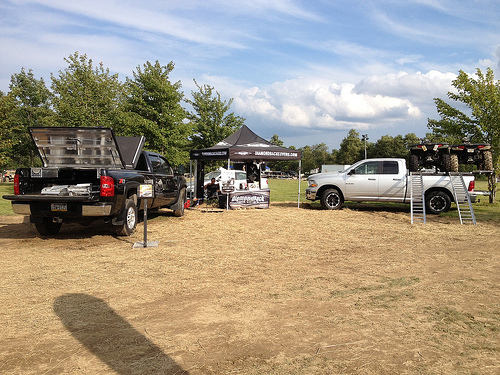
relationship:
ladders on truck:
[402, 172, 483, 227] [275, 137, 499, 233]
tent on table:
[189, 123, 297, 209] [222, 189, 272, 209]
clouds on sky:
[232, 61, 497, 136] [243, 49, 263, 65]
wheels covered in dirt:
[481, 150, 493, 175] [481, 149, 492, 169]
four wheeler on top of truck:
[404, 141, 492, 176] [303, 157, 492, 214]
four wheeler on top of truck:
[404, 141, 492, 176] [2, 127, 186, 236]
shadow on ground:
[46, 282, 202, 374] [3, 202, 497, 366]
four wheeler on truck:
[404, 141, 492, 176] [294, 151, 477, 221]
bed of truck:
[11, 167, 110, 203] [2, 127, 186, 236]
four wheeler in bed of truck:
[404, 141, 492, 176] [321, 140, 461, 242]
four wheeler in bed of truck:
[404, 140, 454, 170] [321, 140, 461, 242]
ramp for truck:
[408, 170, 425, 227] [306, 159, 478, 214]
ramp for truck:
[447, 172, 474, 225] [306, 159, 478, 214]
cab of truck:
[307, 157, 407, 210] [306, 159, 478, 214]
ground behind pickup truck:
[0, 176, 496, 373] [10, 127, 185, 238]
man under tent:
[199, 173, 221, 201] [210, 124, 310, 207]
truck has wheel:
[301, 146, 486, 222] [320, 186, 345, 209]